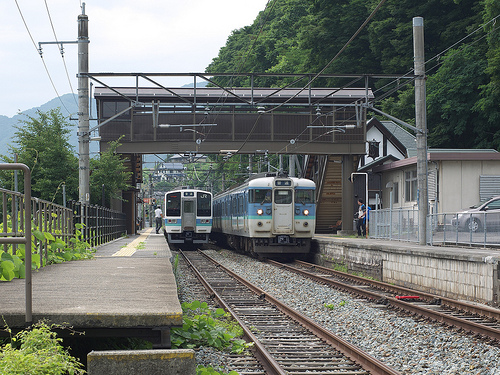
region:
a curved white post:
[342, 166, 378, 243]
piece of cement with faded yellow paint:
[80, 342, 212, 372]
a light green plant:
[0, 324, 91, 370]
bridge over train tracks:
[82, 64, 397, 253]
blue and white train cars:
[134, 150, 346, 282]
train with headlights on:
[207, 160, 339, 274]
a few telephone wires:
[20, 0, 85, 131]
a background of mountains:
[3, 85, 140, 181]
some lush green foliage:
[213, 0, 493, 162]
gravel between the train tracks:
[251, 267, 400, 362]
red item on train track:
[387, 273, 428, 325]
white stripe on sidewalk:
[70, 225, 155, 292]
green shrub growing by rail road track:
[162, 295, 267, 373]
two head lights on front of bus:
[240, 206, 317, 219]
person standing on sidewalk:
[327, 189, 378, 253]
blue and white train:
[247, 171, 321, 237]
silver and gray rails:
[5, 198, 120, 255]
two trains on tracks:
[153, 176, 309, 268]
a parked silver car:
[441, 182, 496, 236]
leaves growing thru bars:
[3, 210, 97, 268]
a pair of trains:
[138, 147, 363, 290]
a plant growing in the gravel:
[173, 294, 261, 361]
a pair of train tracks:
[211, 262, 396, 369]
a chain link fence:
[375, 200, 490, 249]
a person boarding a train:
[141, 183, 199, 239]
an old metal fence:
[0, 169, 133, 268]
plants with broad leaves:
[0, 205, 86, 275]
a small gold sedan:
[433, 187, 499, 228]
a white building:
[321, 87, 443, 207]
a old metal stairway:
[308, 127, 383, 247]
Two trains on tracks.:
[152, 164, 329, 274]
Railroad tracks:
[179, 248, 499, 374]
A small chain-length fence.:
[365, 205, 499, 250]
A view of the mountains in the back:
[0, 52, 249, 204]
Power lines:
[14, 1, 116, 188]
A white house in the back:
[150, 160, 194, 188]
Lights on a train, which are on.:
[250, 207, 315, 218]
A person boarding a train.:
[149, 199, 179, 236]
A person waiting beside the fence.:
[352, 192, 367, 237]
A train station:
[2, 0, 497, 373]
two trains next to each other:
[153, 175, 330, 262]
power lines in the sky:
[1, 2, 108, 162]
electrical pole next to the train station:
[72, 3, 95, 240]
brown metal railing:
[0, 156, 80, 323]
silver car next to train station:
[440, 192, 499, 235]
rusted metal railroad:
[175, 235, 393, 373]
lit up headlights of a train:
[250, 206, 320, 219]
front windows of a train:
[249, 189, 319, 202]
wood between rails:
[241, 305, 291, 333]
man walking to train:
[145, 199, 170, 233]